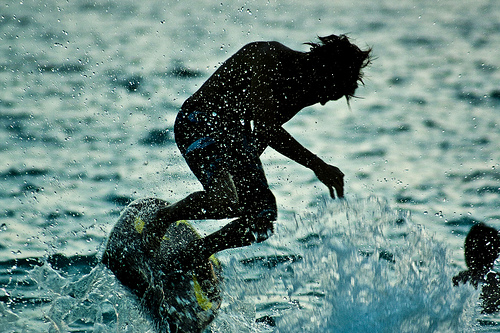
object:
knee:
[202, 182, 241, 221]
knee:
[236, 205, 277, 241]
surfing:
[98, 30, 383, 332]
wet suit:
[152, 41, 324, 265]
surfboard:
[99, 197, 223, 331]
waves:
[0, 194, 498, 332]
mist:
[135, 41, 289, 303]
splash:
[0, 190, 499, 332]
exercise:
[95, 32, 379, 332]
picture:
[0, 1, 499, 332]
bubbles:
[141, 160, 148, 167]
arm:
[236, 40, 318, 168]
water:
[0, 0, 499, 332]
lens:
[0, 0, 499, 332]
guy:
[140, 32, 378, 278]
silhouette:
[96, 32, 379, 332]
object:
[448, 222, 499, 327]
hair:
[296, 32, 379, 111]